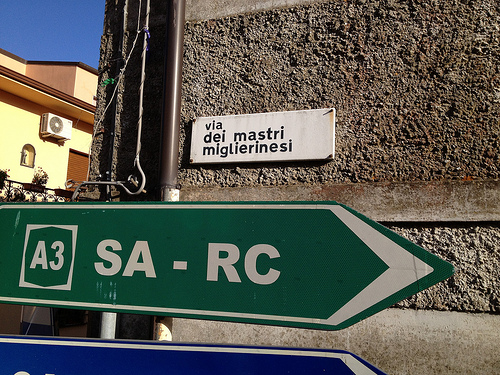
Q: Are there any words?
A: Yes, there are words.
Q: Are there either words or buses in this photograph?
A: Yes, there are words.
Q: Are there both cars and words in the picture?
A: No, there are words but no cars.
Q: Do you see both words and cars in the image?
A: No, there are words but no cars.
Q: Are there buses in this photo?
A: No, there are no buses.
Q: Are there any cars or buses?
A: No, there are no buses or cars.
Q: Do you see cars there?
A: No, there are no cars.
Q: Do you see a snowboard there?
A: No, there are no snowboards.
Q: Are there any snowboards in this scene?
A: No, there are no snowboards.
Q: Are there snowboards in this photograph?
A: No, there are no snowboards.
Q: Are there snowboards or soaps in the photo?
A: No, there are no snowboards or soaps.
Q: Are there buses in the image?
A: No, there are no buses.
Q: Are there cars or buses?
A: No, there are no buses or cars.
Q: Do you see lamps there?
A: No, there are no lamps.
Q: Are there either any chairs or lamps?
A: No, there are no lamps or chairs.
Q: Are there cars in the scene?
A: No, there are no cars.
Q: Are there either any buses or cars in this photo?
A: No, there are no cars or buses.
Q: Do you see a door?
A: Yes, there is a door.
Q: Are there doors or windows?
A: Yes, there is a door.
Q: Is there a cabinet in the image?
A: No, there are no cabinets.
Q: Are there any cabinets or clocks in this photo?
A: No, there are no cabinets or clocks.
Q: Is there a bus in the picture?
A: No, there are no buses.